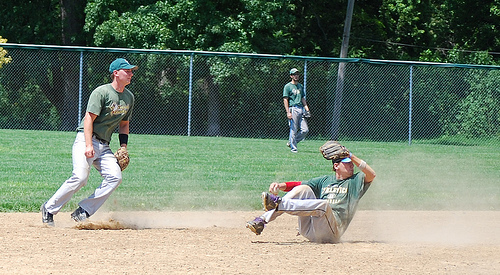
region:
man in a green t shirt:
[37, 35, 164, 227]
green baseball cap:
[105, 54, 140, 79]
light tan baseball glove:
[112, 142, 138, 178]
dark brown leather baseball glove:
[315, 136, 352, 161]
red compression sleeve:
[279, 174, 307, 191]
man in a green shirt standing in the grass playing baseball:
[277, 64, 314, 159]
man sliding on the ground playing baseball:
[240, 139, 384, 254]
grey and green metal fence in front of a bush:
[400, 57, 497, 157]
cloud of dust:
[378, 151, 498, 247]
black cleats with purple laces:
[240, 185, 282, 242]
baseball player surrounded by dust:
[200, 120, 426, 246]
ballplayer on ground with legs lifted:
[240, 135, 405, 246]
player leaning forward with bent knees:
[35, 45, 145, 235]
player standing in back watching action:
[276, 57, 316, 157]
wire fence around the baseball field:
[40, 35, 417, 255]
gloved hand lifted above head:
[287, 131, 397, 241]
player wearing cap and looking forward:
[95, 45, 141, 96]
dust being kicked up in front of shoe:
[30, 45, 155, 250]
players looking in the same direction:
[230, 55, 390, 255]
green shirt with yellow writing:
[312, 162, 362, 232]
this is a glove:
[321, 143, 343, 161]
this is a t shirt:
[284, 86, 304, 106]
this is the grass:
[153, 133, 265, 188]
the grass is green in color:
[163, 137, 259, 199]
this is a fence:
[171, 49, 255, 128]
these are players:
[106, 65, 351, 245]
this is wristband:
[116, 129, 130, 147]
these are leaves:
[129, 13, 267, 39]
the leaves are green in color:
[122, 15, 252, 46]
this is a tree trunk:
[56, 1, 84, 104]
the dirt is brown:
[133, 231, 216, 271]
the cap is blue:
[101, 50, 148, 78]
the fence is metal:
[160, 38, 230, 153]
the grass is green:
[146, 142, 196, 174]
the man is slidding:
[209, 110, 401, 271]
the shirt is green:
[71, 72, 147, 149]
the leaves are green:
[142, 15, 224, 35]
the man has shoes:
[28, 192, 113, 233]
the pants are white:
[55, 126, 128, 223]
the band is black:
[109, 124, 139, 152]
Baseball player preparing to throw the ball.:
[227, 132, 392, 258]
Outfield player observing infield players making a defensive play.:
[266, 48, 320, 151]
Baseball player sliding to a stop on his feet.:
[36, 22, 168, 247]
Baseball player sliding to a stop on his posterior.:
[213, 129, 396, 250]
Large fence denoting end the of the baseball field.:
[339, 32, 499, 164]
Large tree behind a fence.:
[141, 0, 281, 140]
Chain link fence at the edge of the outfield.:
[330, 45, 499, 145]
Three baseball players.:
[34, 25, 409, 243]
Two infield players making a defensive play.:
[10, 37, 397, 230]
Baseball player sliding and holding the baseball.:
[218, 132, 422, 239]